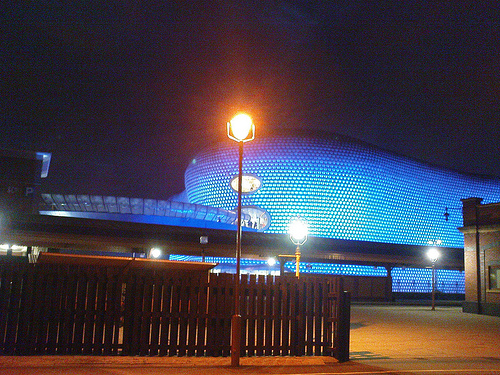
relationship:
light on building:
[351, 195, 374, 204] [149, 121, 489, 303]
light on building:
[327, 203, 330, 208] [189, 142, 466, 274]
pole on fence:
[214, 137, 268, 353] [14, 238, 348, 366]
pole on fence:
[111, 267, 119, 354] [3, 260, 351, 360]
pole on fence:
[228, 137, 245, 366] [84, 269, 292, 355]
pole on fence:
[249, 275, 300, 334] [3, 260, 351, 360]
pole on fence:
[188, 270, 214, 350] [7, 252, 334, 368]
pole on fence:
[214, 274, 232, 353] [56, 257, 296, 339]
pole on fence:
[281, 218, 312, 272] [251, 274, 356, 366]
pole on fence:
[272, 275, 282, 354] [0, 263, 343, 355]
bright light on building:
[265, 255, 277, 267] [166, 131, 498, 300]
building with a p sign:
[4, 143, 47, 217] [20, 182, 37, 199]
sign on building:
[20, 182, 37, 199] [4, 143, 47, 217]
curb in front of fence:
[4, 350, 344, 373] [7, 252, 334, 368]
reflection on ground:
[339, 318, 491, 373] [328, 302, 499, 372]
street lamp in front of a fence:
[209, 110, 256, 350] [60, 261, 326, 351]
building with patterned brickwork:
[166, 131, 498, 300] [181, 135, 498, 298]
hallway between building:
[23, 187, 263, 232] [166, 131, 498, 300]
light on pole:
[213, 112, 272, 158] [223, 131, 257, 369]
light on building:
[190, 153, 200, 167] [184, 137, 493, 287]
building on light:
[166, 131, 498, 300] [301, 175, 408, 233]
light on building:
[223, 171, 265, 194] [166, 131, 498, 300]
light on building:
[415, 170, 423, 176] [8, 127, 498, 303]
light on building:
[290, 175, 350, 202] [395, 183, 428, 208]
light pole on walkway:
[419, 239, 448, 319] [1, 240, 497, 375]